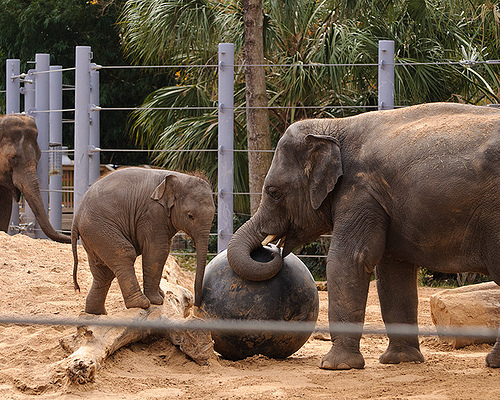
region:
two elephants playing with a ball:
[58, 103, 495, 388]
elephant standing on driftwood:
[32, 135, 225, 391]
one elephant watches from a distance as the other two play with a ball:
[3, 5, 495, 381]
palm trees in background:
[0, 0, 496, 198]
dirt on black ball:
[185, 210, 320, 370]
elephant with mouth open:
[191, 87, 491, 392]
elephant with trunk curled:
[206, 15, 492, 386]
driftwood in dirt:
[10, 257, 240, 392]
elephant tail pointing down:
[50, 140, 215, 345]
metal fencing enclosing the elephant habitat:
[1, 23, 493, 257]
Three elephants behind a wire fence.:
[0, 107, 496, 362]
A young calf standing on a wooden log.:
[65, 165, 210, 350]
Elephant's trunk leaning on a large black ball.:
[200, 245, 315, 350]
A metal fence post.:
[215, 85, 230, 245]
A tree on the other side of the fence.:
[245, 90, 265, 225]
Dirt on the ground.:
[15, 241, 67, 311]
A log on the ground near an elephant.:
[431, 284, 494, 335]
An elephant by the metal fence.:
[0, 115, 50, 235]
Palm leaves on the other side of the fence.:
[140, 85, 215, 160]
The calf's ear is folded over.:
[150, 180, 175, 206]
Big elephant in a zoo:
[228, 102, 499, 369]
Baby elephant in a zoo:
[71, 165, 216, 315]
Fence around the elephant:
[0, 40, 499, 275]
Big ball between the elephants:
[203, 244, 318, 358]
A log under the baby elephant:
[67, 262, 213, 387]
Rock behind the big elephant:
[431, 282, 498, 349]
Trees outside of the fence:
[1, 4, 496, 279]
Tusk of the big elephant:
[261, 234, 276, 245]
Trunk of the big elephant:
[227, 216, 284, 281]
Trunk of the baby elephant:
[191, 232, 208, 307]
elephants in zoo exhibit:
[1, 49, 488, 393]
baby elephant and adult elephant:
[55, 107, 498, 369]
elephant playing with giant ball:
[210, 102, 497, 383]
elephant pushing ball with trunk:
[209, 108, 445, 398]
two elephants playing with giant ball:
[68, 109, 433, 345]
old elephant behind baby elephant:
[0, 104, 205, 340]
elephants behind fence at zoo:
[67, 53, 444, 357]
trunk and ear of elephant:
[210, 105, 358, 302]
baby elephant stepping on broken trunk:
[65, 153, 230, 358]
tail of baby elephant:
[61, 217, 91, 302]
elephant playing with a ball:
[201, 95, 497, 363]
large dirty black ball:
[196, 238, 315, 358]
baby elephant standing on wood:
[58, 167, 230, 361]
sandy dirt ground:
[21, 214, 484, 398]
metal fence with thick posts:
[16, 41, 483, 265]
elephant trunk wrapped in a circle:
[226, 208, 287, 280]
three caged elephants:
[3, 37, 493, 398]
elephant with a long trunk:
[1, 94, 64, 246]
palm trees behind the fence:
[95, 0, 424, 250]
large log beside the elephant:
[426, 270, 497, 345]